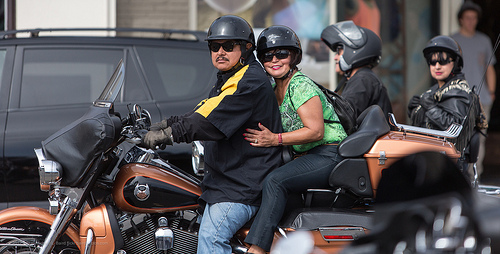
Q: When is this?
A: Daytime.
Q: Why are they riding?
A: Travelling.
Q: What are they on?
A: Motorcycle.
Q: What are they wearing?
A: Helmets.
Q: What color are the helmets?
A: Black.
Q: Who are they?
A: People.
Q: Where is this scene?
A: On the street.